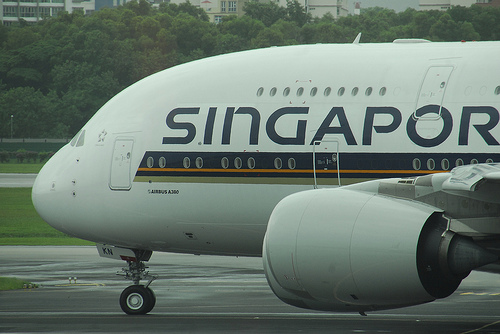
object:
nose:
[30, 78, 143, 249]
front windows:
[62, 127, 89, 147]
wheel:
[119, 284, 155, 316]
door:
[411, 61, 457, 120]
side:
[31, 32, 500, 313]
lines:
[132, 167, 446, 175]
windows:
[271, 157, 284, 169]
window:
[246, 156, 257, 169]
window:
[233, 155, 243, 169]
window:
[220, 157, 230, 170]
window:
[194, 155, 204, 169]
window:
[181, 155, 190, 170]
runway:
[0, 244, 500, 334]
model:
[94, 244, 138, 262]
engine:
[260, 186, 497, 311]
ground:
[0, 244, 499, 334]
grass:
[0, 278, 34, 291]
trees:
[0, 0, 217, 142]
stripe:
[132, 150, 499, 186]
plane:
[31, 26, 500, 316]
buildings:
[1, 0, 390, 22]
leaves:
[0, 0, 204, 135]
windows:
[256, 85, 386, 96]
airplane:
[31, 33, 499, 314]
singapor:
[164, 104, 498, 145]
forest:
[0, 0, 500, 139]